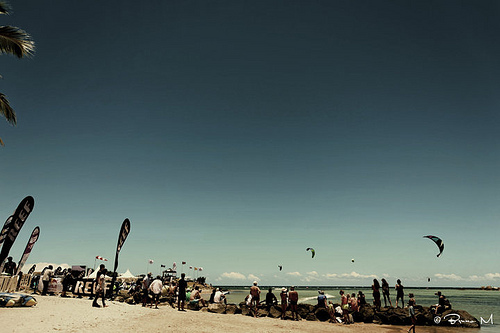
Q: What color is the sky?
A: Blue.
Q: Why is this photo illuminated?
A: Sunlight.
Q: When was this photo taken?
A: During the day.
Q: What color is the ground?
A: Brown.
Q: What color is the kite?
A: Green.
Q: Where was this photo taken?
A: At a beach.